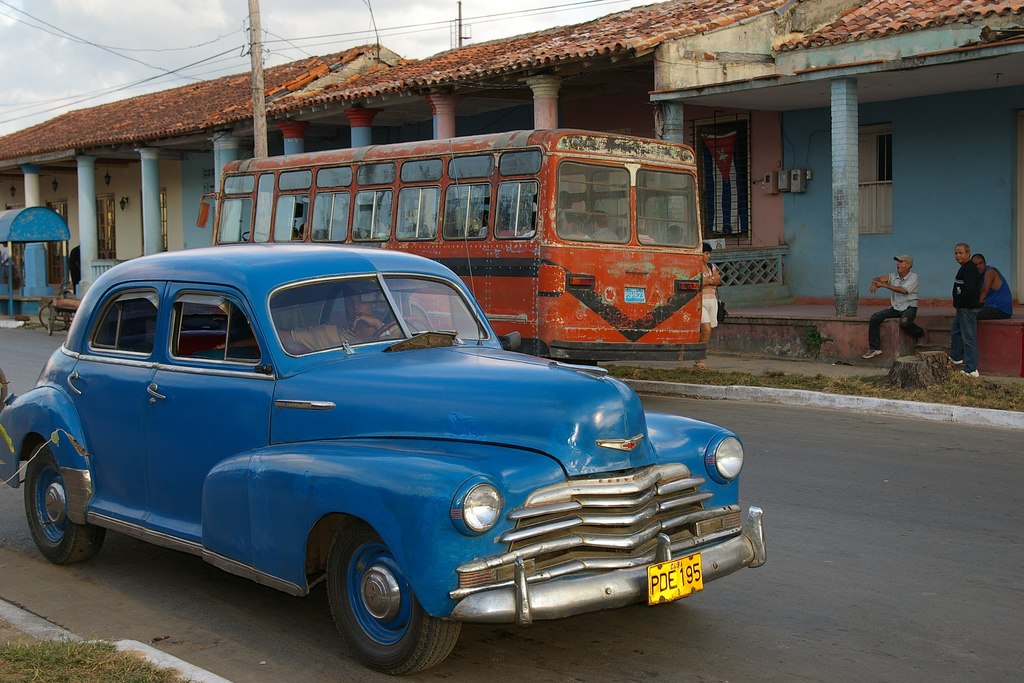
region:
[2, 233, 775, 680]
blue vintage car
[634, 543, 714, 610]
yellow license plate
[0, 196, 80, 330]
blue metal bus stop covering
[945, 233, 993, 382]
man standing up in front of step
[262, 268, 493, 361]
windshield on front of blue car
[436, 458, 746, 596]
metal grill on front of car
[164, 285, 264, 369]
side window on vintage car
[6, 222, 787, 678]
blue vehicle on a street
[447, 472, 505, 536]
front headlight on a vehicle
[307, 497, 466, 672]
front wheel on a vehicle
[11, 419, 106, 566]
rear wheel on a vehicle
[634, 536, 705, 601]
front licence plate on a vehicle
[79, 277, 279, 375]
side windows on a vehicle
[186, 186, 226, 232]
side rear view mirror on a bus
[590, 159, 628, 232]
a window on the bus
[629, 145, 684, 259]
a window on the bus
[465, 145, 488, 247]
a window on the bus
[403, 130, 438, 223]
a window on the bus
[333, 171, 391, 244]
a window on the bus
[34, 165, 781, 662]
cars on the road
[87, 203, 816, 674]
blue car on the road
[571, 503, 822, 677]
license plate on the car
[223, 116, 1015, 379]
red bus on the road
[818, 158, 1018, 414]
people sitting down on a bench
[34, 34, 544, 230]
tiles on the roof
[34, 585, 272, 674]
grass on the ground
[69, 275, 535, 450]
windows on the car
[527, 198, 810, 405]
black design on the bus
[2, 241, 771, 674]
old blue car parked on street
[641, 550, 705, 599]
yellow license plate on car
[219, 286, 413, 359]
man sitting inside blue car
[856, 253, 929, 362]
man in white shirt and black pants sitting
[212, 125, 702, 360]
old orange bus parked on street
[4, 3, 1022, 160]
orange ceramic roof tiles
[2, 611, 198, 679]
parched grass near curb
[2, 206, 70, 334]
blue covered bus stop near curb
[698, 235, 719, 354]
woman in pink shirt and white shorts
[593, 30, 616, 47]
A shingle on a roof.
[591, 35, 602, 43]
A shingle on a roof.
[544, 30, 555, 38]
A shingle on a roof.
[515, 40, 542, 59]
A shingle on a roof.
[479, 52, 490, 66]
A shingle on a roof.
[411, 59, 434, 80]
A shingle on a roof.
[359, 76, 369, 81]
A shingle on a roof.